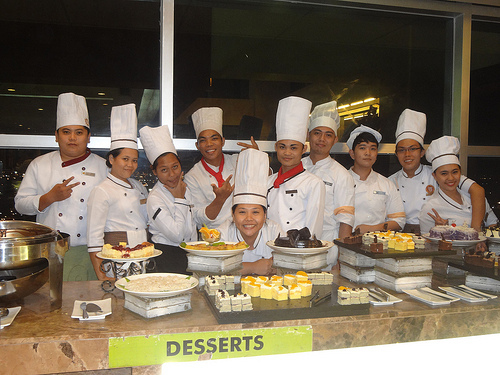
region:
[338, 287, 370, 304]
desserts on a marble table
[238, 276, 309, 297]
desserts on a marble table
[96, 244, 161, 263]
desserts on a marble table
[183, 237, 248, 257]
desserts on a marble table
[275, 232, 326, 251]
desserts on a marble table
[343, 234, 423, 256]
desserts on a marble table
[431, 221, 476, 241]
desserts on a marble table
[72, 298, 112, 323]
serving platter on a table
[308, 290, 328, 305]
tongs on a marble table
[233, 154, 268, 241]
asian person in a chefs hat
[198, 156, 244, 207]
the scarf is red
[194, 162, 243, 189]
the scarf is red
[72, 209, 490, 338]
food on the countertop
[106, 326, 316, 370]
black letters on green sign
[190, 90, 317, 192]
chefs in red scarves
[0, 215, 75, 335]
fondue pot on left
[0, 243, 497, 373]
brownish marble counter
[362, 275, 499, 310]
white napkins with silverware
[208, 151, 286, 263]
middle chef leaning on counter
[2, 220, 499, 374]
counter full of desserts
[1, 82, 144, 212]
circular lights reflected in window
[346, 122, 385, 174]
black hair poking out of chef hat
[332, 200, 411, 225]
beige stripes on sleeves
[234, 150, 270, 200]
a white hat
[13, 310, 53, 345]
the counter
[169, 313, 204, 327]
the marble counter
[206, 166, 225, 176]
man is wearing a red tie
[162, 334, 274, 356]
black letters on the yellow sign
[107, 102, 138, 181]
a women wearing a hat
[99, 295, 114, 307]
the napkin is white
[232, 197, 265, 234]
women is smiling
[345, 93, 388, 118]
lights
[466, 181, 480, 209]
the girls arm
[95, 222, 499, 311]
the desserts on the table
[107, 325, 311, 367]
the DESSERTS sign on the side of the table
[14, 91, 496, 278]
the group of chefs posing for a picture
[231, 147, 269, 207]
the white chef's hat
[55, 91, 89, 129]
the white chef's hat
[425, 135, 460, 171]
the white chef's hat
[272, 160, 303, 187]
the red fabric around the man's neck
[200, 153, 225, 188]
the red fabric around the man's neck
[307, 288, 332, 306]
the tongs next to the desserts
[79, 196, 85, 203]
the button on the chef's jacket